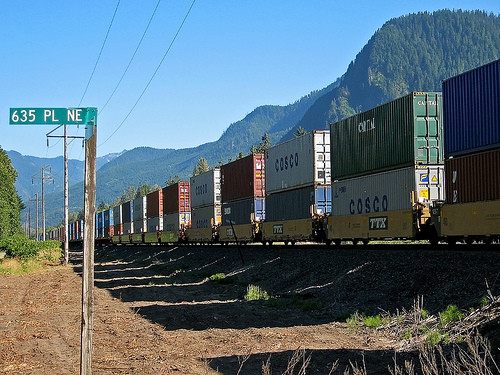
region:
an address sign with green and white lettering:
[4, 73, 101, 373]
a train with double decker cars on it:
[10, 7, 497, 344]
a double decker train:
[35, 49, 495, 267]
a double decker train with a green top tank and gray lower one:
[323, 87, 447, 245]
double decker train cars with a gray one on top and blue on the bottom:
[257, 115, 337, 253]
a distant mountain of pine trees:
[348, 4, 498, 76]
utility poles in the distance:
[20, 160, 61, 248]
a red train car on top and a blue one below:
[217, 144, 262, 244]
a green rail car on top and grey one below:
[329, 82, 447, 258]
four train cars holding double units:
[119, 180, 191, 247]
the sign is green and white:
[0, 100, 195, 222]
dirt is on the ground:
[122, 298, 177, 347]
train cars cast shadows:
[110, 188, 210, 363]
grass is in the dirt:
[210, 278, 275, 344]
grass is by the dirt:
[10, 220, 92, 326]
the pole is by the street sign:
[54, 102, 150, 319]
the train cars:
[182, 138, 414, 333]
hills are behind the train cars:
[200, 105, 422, 225]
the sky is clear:
[153, 70, 328, 132]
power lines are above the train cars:
[45, 49, 432, 164]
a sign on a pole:
[32, 80, 147, 212]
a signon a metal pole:
[55, 90, 115, 194]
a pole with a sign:
[22, 75, 154, 237]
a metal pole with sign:
[60, 82, 157, 207]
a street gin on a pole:
[17, 84, 103, 191]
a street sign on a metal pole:
[8, 58, 178, 283]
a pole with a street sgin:
[43, 86, 125, 206]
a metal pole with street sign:
[27, 73, 107, 244]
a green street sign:
[4, 76, 179, 208]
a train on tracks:
[173, 63, 483, 327]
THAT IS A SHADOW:
[154, 302, 329, 326]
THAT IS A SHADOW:
[327, 351, 475, 371]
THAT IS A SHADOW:
[205, 268, 249, 308]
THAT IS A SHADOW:
[174, 266, 202, 283]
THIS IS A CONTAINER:
[195, 172, 212, 222]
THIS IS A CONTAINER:
[264, 141, 319, 235]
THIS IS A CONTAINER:
[325, 101, 417, 231]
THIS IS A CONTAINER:
[162, 189, 182, 237]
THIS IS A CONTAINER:
[148, 198, 162, 229]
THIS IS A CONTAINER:
[121, 206, 136, 228]